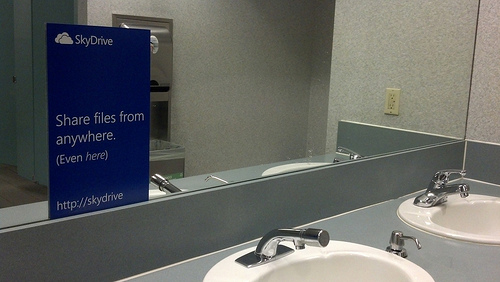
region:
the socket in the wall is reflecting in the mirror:
[375, 78, 404, 120]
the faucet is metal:
[232, 207, 334, 272]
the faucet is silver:
[232, 223, 334, 273]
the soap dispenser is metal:
[390, 225, 425, 255]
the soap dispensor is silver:
[382, 221, 423, 256]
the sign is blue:
[37, 15, 160, 217]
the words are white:
[52, 102, 145, 172]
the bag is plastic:
[150, 136, 189, 158]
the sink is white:
[290, 256, 368, 278]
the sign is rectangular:
[39, 16, 156, 216]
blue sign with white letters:
[50, 25, 154, 218]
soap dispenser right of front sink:
[391, 221, 423, 261]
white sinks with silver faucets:
[201, 165, 498, 280]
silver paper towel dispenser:
[116, 17, 176, 138]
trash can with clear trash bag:
[137, 133, 189, 180]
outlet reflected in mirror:
[383, 85, 400, 118]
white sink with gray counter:
[114, 164, 497, 279]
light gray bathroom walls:
[0, 0, 499, 187]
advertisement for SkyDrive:
[51, 26, 151, 208]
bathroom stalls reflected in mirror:
[0, 0, 76, 187]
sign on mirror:
[46, 22, 147, 216]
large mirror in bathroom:
[0, 4, 478, 280]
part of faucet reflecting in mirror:
[151, 169, 183, 194]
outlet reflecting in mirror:
[384, 87, 400, 117]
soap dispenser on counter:
[387, 225, 422, 262]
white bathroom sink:
[198, 222, 433, 277]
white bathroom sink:
[401, 170, 499, 246]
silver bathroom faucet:
[410, 165, 468, 207]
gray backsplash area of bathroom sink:
[0, 140, 465, 277]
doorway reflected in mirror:
[0, 5, 87, 213]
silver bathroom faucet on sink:
[401, 163, 472, 214]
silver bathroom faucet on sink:
[231, 216, 333, 278]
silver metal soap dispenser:
[377, 226, 424, 263]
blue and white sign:
[27, 16, 168, 223]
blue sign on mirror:
[39, 21, 157, 224]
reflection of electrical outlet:
[381, 84, 403, 122]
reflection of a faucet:
[149, 159, 187, 206]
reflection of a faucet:
[324, 140, 375, 168]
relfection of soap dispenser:
[195, 166, 237, 188]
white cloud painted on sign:
[51, 30, 78, 47]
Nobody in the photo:
[7, 3, 496, 275]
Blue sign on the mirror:
[20, 6, 182, 215]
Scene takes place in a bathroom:
[11, 7, 486, 274]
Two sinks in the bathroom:
[197, 165, 497, 280]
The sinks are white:
[196, 177, 496, 277]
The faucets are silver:
[237, 159, 485, 267]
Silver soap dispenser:
[375, 208, 433, 266]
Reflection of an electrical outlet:
[367, 68, 409, 123]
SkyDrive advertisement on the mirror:
[33, 19, 135, 54]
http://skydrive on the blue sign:
[45, 183, 149, 220]